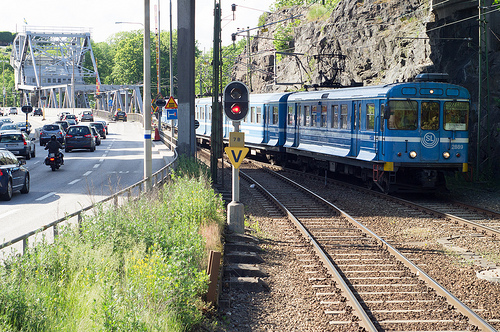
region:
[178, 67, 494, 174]
the train on the tracks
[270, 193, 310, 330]
the gravel on the tracks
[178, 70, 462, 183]
the train is blue and white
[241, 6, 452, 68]
the power cables above the train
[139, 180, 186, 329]
the weeds beside the road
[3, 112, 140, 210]
the cars on the road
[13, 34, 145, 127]
the bridge in the background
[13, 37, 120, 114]
the bridge is made of steel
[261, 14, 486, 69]
the rock face beside the train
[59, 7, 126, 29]
the sky is clear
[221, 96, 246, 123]
stop light is red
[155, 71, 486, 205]
blue train on tracks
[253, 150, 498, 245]
track is holding blue train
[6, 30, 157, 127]
bridge is in distance on road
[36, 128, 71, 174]
motorcycle on road between cars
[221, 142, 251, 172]
letter v on sign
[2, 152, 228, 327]
bush of weeds between road and track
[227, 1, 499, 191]
rock wall to the right of train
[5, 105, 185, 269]
road to the left of train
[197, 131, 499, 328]
gravel in amongst tracks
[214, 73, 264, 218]
red light beside train tracks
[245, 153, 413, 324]
train tracks on the ground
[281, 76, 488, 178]
blue passenger train on train tracks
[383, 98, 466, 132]
front windshield of a blue passenger train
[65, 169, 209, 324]
overgrown weeds beside a train track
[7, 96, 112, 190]
traffic driving on a road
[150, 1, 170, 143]
train crossing gate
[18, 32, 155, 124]
metal train bridge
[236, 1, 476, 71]
electrical wires above train tracks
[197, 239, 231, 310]
wooden post beside a train track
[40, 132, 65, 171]
Man riding motorcycle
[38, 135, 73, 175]
Motorcycle in front of blue car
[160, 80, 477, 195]
Blue train on train tracks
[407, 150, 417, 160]
Light on train is red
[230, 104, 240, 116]
Red light is on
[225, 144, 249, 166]
Yellow train traffic sign below traffic light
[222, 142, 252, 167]
Yellow train traffic sign is triangular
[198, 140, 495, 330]
Train tracks next to train traffic light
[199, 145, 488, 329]
Train tracks next to yellow train traffic sign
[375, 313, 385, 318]
Small rock on train tracks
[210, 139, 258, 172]
yellow triangle train sign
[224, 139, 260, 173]
V on the yellow sign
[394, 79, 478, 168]
three lights on the train car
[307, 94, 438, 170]
train is blue with white stripe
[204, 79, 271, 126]
signal light is red for train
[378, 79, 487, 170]
train lights are on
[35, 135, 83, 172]
motorcycle riding towards the bridge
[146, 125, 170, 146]
caution cone on side of road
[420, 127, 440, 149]
SL on the front of train car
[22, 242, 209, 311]
yellow flowers in the weeds